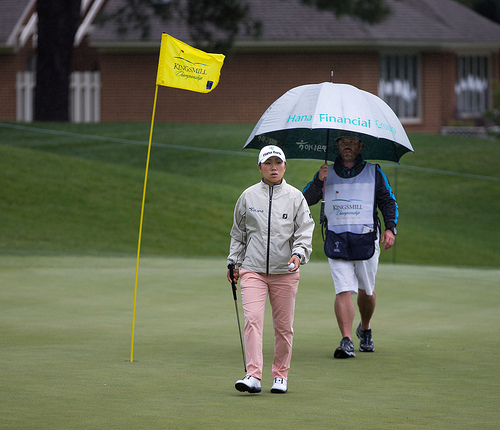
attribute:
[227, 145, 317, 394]
woman — walking, playing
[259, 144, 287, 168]
hat — white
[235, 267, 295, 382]
pants — pink, long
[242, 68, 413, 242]
umbrella — big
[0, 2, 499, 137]
building — brown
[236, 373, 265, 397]
shoe — white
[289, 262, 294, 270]
ball — white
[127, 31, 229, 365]
flag — yellow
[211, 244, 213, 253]
grass — green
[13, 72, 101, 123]
fence — white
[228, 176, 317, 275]
jacket — white